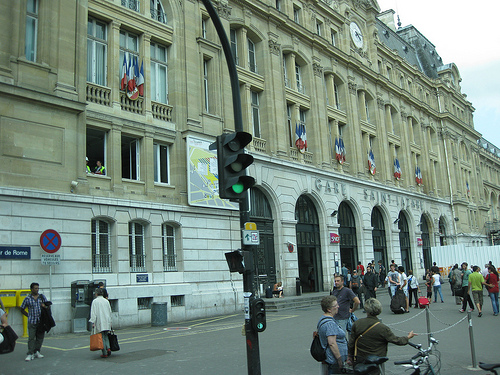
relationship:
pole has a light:
[201, 2, 260, 374] [209, 132, 254, 202]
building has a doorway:
[3, 2, 495, 342] [296, 246, 323, 294]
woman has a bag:
[89, 289, 121, 356] [90, 335, 105, 350]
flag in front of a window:
[296, 128, 308, 152] [252, 90, 262, 140]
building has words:
[3, 2, 495, 342] [313, 180, 422, 210]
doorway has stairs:
[296, 246, 323, 294] [264, 292, 333, 310]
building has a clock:
[3, 2, 495, 342] [347, 23, 365, 51]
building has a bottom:
[3, 2, 495, 342] [2, 96, 497, 342]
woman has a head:
[89, 289, 121, 356] [94, 289, 104, 296]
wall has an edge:
[3, 1, 499, 331] [2, 83, 88, 116]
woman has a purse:
[89, 289, 121, 356] [109, 336, 119, 353]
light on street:
[209, 132, 254, 202] [3, 280, 499, 374]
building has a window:
[3, 2, 495, 342] [252, 90, 262, 140]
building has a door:
[3, 2, 495, 342] [296, 245, 320, 293]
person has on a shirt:
[349, 299, 414, 375] [473, 290, 485, 307]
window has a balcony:
[252, 90, 262, 140] [89, 84, 112, 108]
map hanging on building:
[285, 245, 294, 254] [3, 2, 495, 342]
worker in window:
[86, 161, 107, 176] [252, 90, 262, 140]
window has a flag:
[252, 90, 262, 140] [296, 128, 308, 152]